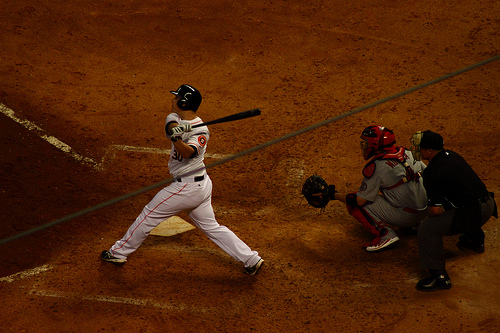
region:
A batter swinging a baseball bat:
[99, 63, 274, 278]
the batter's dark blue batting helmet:
[167, 80, 202, 115]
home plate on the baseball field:
[167, 217, 190, 237]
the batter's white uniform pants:
[100, 173, 275, 269]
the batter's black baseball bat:
[206, 105, 262, 127]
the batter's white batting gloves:
[170, 119, 197, 142]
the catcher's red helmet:
[357, 115, 402, 155]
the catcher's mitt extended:
[300, 165, 337, 210]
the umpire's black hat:
[410, 127, 447, 156]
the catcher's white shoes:
[363, 232, 399, 256]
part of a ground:
[298, 243, 355, 302]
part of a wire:
[265, 121, 294, 158]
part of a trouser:
[222, 226, 242, 259]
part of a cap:
[419, 131, 442, 151]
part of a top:
[398, 180, 419, 206]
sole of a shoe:
[247, 249, 272, 286]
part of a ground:
[320, 265, 360, 309]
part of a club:
[232, 109, 270, 135]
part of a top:
[158, 154, 192, 171]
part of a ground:
[243, 192, 280, 234]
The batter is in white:
[84, 70, 296, 297]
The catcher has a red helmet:
[298, 97, 422, 264]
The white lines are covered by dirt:
[58, 94, 321, 320]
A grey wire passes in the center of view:
[16, 45, 491, 252]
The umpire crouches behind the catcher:
[401, 112, 492, 297]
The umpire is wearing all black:
[392, 111, 484, 296]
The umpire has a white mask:
[391, 110, 474, 291]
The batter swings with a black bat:
[96, 52, 286, 297]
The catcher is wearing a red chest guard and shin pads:
[303, 104, 440, 251]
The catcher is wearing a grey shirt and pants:
[311, 119, 425, 254]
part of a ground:
[288, 57, 349, 101]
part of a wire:
[247, 130, 266, 154]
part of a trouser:
[213, 222, 236, 247]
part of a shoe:
[254, 265, 269, 285]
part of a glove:
[308, 187, 336, 232]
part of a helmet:
[371, 138, 391, 164]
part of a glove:
[174, 129, 190, 138]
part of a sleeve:
[191, 131, 209, 157]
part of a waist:
[185, 175, 199, 185]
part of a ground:
[273, 255, 307, 291]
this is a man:
[100, 81, 267, 274]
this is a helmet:
[178, 82, 197, 106]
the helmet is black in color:
[192, 95, 200, 101]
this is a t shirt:
[436, 159, 466, 195]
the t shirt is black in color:
[436, 162, 462, 188]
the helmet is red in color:
[373, 131, 387, 141]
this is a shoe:
[420, 274, 447, 289]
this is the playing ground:
[19, 38, 123, 138]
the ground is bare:
[270, 11, 377, 62]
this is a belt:
[196, 176, 203, 179]